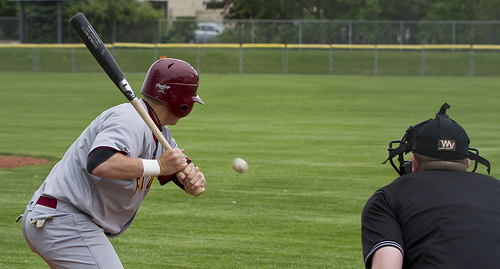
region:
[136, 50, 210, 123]
a red helmet on a man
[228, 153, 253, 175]
a ball flying i the air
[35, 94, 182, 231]
a grey shirt on a batter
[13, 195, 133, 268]
grey pants on a batter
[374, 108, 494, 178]
a black mask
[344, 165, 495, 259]
a black shirt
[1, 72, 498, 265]
mown green grass of a baseball field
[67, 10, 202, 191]
a bat in a batter's hands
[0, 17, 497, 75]
a chain link fence at a baseball field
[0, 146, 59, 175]
the dirt of the pitcher's mound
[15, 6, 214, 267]
baseball player up to bat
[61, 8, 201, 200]
black and wooden baseball bat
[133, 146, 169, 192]
white wrist sweat band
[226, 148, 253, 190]
white baseball in the air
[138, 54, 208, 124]
maroon batter's helmet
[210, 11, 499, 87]
chain link fence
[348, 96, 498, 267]
baseball umpire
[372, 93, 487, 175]
black umpire's baseball hat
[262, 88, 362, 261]
green grass of baseball field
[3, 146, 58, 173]
sand baseball pitcher's mound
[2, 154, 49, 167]
small patch of dirt on field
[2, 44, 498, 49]
yellow top of fencing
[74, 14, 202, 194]
black wooden baseball bat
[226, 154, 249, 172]
baseball flying towards batter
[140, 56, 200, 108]
red helmet on batter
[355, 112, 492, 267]
umpire watching baseball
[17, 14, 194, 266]
batter about to swing baseball bat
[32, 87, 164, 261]
grey uniform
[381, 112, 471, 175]
black facemask and helmet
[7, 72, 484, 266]
green grass on field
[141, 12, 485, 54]
a long grey fence.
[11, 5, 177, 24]
a beautiful bush of trees.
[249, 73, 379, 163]
a big green field.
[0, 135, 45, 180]
a pitchers mound.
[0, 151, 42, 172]
brown dirt is in the pitchers mound.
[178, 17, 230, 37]
a white car is parked.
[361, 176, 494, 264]
a man is wearing a black shirt.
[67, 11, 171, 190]
the player is striking the ball.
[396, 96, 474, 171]
the umpire is wearing a black hat.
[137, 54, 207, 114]
the baseball player is wearing a helmet.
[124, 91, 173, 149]
a brown bat in the man hand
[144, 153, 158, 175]
the man is wearing a wristband around his wrist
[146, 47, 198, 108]
the man is wearing a helmet for protection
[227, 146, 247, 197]
the ball is flying in the air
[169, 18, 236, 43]
there is a car outside the field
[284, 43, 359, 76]
a metal fence is around the field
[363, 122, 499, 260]
the referee is watching the ball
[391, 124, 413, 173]
the man is wearing a headset around his head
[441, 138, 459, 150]
on the back of the hat is written in yellow wv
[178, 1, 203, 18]
brown building back over the fence